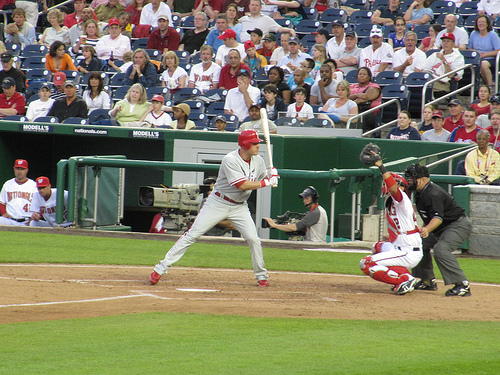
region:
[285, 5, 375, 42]
empty seats for fans in the stadium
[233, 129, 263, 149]
red batter's helmet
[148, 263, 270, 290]
red cleated shoes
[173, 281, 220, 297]
plate at home base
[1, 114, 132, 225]
players in the dugout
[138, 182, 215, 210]
television camera catching the game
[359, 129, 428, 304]
catcher catching the ball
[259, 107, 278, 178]
The bat in the player's hand.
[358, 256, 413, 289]
The knee guard shields the catcher is wearing.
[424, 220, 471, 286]
The gray pants the umpire is wearing.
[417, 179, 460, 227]
The black shirt the umpire is wearing.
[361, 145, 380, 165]
The black glove the catcher is wearing.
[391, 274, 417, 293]
The sneakers the catcher is wearing.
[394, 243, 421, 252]
The black belt the catcher is wearing.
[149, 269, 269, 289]
The red sneakers the batter is wearing.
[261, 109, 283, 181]
a bat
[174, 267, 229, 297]
home plate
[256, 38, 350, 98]
fans in the crowd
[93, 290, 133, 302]
a white line on the baseball field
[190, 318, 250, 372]
the grass on the field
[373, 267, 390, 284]
red pads on the catcher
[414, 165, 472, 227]
the umpire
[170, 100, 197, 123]
women wearing a brown hat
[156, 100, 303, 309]
baseball player up to bat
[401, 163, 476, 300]
umpire with a black mask on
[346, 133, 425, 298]
catcher wearing a black baseball glove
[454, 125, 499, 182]
man watching game wearing a yellow shirt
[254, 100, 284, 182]
a white baseball bat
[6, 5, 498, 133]
a group of baseball fans watching a game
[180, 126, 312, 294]
player in red and white uniform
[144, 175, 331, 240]
television camera and crew in dug out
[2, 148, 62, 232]
two players sitting in dugout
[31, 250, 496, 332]
baseball baseline with homeplate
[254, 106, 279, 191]
a man holding a baseball bat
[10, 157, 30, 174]
a man wearing a red baseball cap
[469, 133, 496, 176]
a woman wearing a yellow shirt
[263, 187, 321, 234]
a man holding a camera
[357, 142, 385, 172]
a man wearing a catchers glove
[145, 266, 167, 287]
a man wearing red shoes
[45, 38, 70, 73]
a woman wearing a orange shirt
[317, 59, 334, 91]
a man touching his face with his hand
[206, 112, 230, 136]
a young boy wearing a baseball cap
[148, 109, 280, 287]
Baseball player holding bat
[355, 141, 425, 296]
Catcher reaching up with his gloved left hand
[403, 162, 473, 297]
Umpire crouching behind the catcher